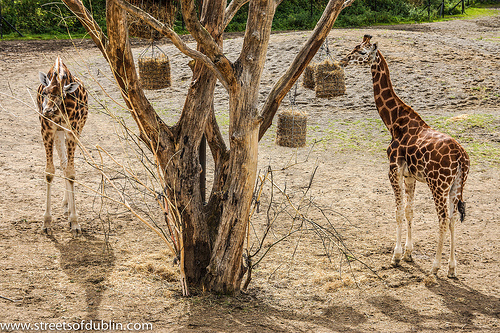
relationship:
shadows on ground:
[87, 262, 105, 301] [323, 177, 344, 203]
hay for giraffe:
[139, 62, 184, 99] [14, 42, 87, 200]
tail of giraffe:
[457, 158, 469, 225] [14, 42, 87, 200]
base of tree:
[202, 280, 262, 295] [202, 70, 252, 138]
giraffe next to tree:
[14, 42, 87, 200] [202, 70, 252, 138]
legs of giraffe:
[44, 170, 79, 209] [14, 42, 87, 200]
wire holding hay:
[145, 38, 162, 51] [139, 62, 184, 99]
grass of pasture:
[42, 32, 63, 42] [400, 10, 452, 34]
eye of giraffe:
[350, 50, 372, 56] [14, 42, 87, 200]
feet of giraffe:
[48, 215, 88, 228] [14, 42, 87, 200]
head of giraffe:
[342, 40, 382, 68] [14, 42, 87, 200]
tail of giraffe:
[447, 155, 475, 171] [14, 42, 87, 200]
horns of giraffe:
[355, 34, 372, 47] [14, 42, 87, 200]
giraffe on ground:
[14, 42, 87, 200] [323, 177, 344, 203]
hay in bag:
[139, 62, 184, 99] [307, 52, 341, 76]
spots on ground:
[359, 10, 468, 67] [323, 177, 344, 203]